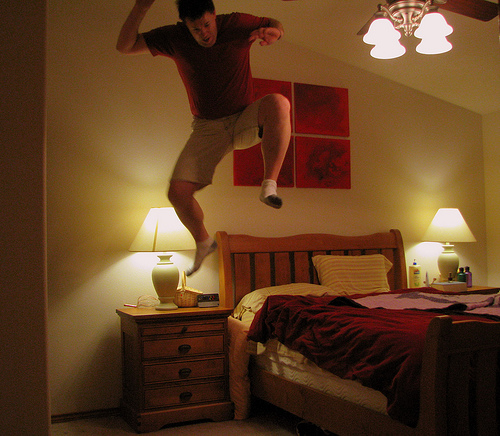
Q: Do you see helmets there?
A: No, there are no helmets.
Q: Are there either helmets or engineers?
A: No, there are no helmets or engineers.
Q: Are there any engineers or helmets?
A: No, there are no helmets or engineers.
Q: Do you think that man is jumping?
A: Yes, the man is jumping.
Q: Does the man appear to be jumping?
A: Yes, the man is jumping.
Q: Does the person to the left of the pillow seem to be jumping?
A: Yes, the man is jumping.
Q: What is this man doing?
A: The man is jumping.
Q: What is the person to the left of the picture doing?
A: The man is jumping.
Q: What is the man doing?
A: The man is jumping.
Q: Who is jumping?
A: The man is jumping.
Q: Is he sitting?
A: No, the man is jumping.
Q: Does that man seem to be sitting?
A: No, the man is jumping.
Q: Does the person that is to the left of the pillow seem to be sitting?
A: No, the man is jumping.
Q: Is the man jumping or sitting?
A: The man is jumping.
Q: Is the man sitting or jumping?
A: The man is jumping.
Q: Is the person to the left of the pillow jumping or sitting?
A: The man is jumping.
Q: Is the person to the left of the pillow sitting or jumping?
A: The man is jumping.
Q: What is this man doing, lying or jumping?
A: The man is jumping.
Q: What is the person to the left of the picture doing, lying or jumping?
A: The man is jumping.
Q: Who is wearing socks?
A: The man is wearing socks.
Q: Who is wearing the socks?
A: The man is wearing socks.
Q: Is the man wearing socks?
A: Yes, the man is wearing socks.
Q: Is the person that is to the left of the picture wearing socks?
A: Yes, the man is wearing socks.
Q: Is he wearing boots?
A: No, the man is wearing socks.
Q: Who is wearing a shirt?
A: The man is wearing a shirt.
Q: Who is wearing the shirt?
A: The man is wearing a shirt.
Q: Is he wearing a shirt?
A: Yes, the man is wearing a shirt.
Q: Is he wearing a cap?
A: No, the man is wearing a shirt.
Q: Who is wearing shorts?
A: The man is wearing shorts.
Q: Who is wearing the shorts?
A: The man is wearing shorts.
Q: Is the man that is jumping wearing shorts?
A: Yes, the man is wearing shorts.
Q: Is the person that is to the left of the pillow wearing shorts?
A: Yes, the man is wearing shorts.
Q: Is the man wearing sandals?
A: No, the man is wearing shorts.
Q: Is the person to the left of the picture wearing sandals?
A: No, the man is wearing shorts.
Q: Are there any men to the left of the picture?
A: Yes, there is a man to the left of the picture.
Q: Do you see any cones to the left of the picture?
A: No, there is a man to the left of the picture.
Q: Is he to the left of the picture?
A: Yes, the man is to the left of the picture.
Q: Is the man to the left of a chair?
A: No, the man is to the left of the picture.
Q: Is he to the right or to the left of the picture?
A: The man is to the left of the picture.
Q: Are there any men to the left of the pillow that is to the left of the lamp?
A: Yes, there is a man to the left of the pillow.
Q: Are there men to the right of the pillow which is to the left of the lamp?
A: No, the man is to the left of the pillow.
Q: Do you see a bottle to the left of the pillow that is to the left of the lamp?
A: No, there is a man to the left of the pillow.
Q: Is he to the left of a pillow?
A: Yes, the man is to the left of a pillow.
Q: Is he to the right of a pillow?
A: No, the man is to the left of a pillow.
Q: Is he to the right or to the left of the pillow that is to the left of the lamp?
A: The man is to the left of the pillow.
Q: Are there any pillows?
A: Yes, there is a pillow.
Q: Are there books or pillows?
A: Yes, there is a pillow.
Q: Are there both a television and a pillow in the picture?
A: No, there is a pillow but no televisions.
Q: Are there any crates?
A: No, there are no crates.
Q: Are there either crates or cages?
A: No, there are no crates or cages.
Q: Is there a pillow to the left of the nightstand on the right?
A: Yes, there is a pillow to the left of the nightstand.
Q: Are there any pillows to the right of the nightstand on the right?
A: No, the pillow is to the left of the nightstand.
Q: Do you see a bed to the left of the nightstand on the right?
A: No, there is a pillow to the left of the nightstand.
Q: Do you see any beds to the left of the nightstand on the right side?
A: No, there is a pillow to the left of the nightstand.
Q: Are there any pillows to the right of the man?
A: Yes, there is a pillow to the right of the man.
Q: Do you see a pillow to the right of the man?
A: Yes, there is a pillow to the right of the man.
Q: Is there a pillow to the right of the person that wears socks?
A: Yes, there is a pillow to the right of the man.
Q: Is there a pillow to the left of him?
A: No, the pillow is to the right of the man.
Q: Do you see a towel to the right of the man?
A: No, there is a pillow to the right of the man.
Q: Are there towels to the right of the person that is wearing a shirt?
A: No, there is a pillow to the right of the man.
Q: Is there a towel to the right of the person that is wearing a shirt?
A: No, there is a pillow to the right of the man.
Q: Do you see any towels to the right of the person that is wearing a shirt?
A: No, there is a pillow to the right of the man.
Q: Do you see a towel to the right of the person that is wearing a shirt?
A: No, there is a pillow to the right of the man.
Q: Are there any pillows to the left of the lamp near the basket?
A: No, the pillow is to the right of the lamp.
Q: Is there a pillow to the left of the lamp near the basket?
A: No, the pillow is to the right of the lamp.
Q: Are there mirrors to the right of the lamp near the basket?
A: No, there is a pillow to the right of the lamp.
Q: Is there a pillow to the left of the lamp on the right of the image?
A: Yes, there is a pillow to the left of the lamp.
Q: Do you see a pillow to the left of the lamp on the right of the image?
A: Yes, there is a pillow to the left of the lamp.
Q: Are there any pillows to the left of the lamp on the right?
A: Yes, there is a pillow to the left of the lamp.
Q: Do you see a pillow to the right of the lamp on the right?
A: No, the pillow is to the left of the lamp.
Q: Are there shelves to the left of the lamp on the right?
A: No, there is a pillow to the left of the lamp.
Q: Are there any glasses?
A: No, there are no glasses.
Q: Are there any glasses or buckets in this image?
A: No, there are no glasses or buckets.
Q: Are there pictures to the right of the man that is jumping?
A: Yes, there is a picture to the right of the man.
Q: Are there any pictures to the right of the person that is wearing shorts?
A: Yes, there is a picture to the right of the man.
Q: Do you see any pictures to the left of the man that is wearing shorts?
A: No, the picture is to the right of the man.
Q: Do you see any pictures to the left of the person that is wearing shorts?
A: No, the picture is to the right of the man.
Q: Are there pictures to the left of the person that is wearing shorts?
A: No, the picture is to the right of the man.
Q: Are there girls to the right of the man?
A: No, there is a picture to the right of the man.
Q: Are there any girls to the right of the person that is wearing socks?
A: No, there is a picture to the right of the man.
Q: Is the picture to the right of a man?
A: Yes, the picture is to the right of a man.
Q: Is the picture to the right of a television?
A: No, the picture is to the right of a man.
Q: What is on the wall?
A: The picture is on the wall.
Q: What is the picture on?
A: The picture is on the wall.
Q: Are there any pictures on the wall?
A: Yes, there is a picture on the wall.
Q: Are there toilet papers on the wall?
A: No, there is a picture on the wall.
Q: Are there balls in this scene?
A: No, there are no balls.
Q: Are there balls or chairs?
A: No, there are no balls or chairs.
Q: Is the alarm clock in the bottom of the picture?
A: Yes, the alarm clock is in the bottom of the image.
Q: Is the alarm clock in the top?
A: No, the alarm clock is in the bottom of the image.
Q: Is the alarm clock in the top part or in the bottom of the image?
A: The alarm clock is in the bottom of the image.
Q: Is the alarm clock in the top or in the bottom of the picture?
A: The alarm clock is in the bottom of the image.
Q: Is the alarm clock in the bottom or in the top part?
A: The alarm clock is in the bottom of the image.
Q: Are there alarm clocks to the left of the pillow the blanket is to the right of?
A: Yes, there is an alarm clock to the left of the pillow.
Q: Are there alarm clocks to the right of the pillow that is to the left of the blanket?
A: No, the alarm clock is to the left of the pillow.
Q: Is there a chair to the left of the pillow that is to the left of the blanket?
A: No, there is an alarm clock to the left of the pillow.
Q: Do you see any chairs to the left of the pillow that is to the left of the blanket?
A: No, there is an alarm clock to the left of the pillow.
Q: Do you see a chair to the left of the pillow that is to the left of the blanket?
A: No, there is an alarm clock to the left of the pillow.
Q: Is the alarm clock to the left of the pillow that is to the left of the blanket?
A: Yes, the alarm clock is to the left of the pillow.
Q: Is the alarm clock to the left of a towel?
A: No, the alarm clock is to the left of the pillow.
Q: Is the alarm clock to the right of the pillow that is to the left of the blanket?
A: No, the alarm clock is to the left of the pillow.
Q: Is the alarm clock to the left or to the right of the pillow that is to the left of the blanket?
A: The alarm clock is to the left of the pillow.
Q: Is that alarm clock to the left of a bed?
A: No, the alarm clock is to the left of the mattress.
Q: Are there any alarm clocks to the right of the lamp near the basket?
A: Yes, there is an alarm clock to the right of the lamp.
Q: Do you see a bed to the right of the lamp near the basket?
A: No, there is an alarm clock to the right of the lamp.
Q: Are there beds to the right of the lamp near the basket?
A: No, there is an alarm clock to the right of the lamp.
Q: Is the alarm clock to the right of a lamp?
A: Yes, the alarm clock is to the right of a lamp.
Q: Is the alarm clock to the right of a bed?
A: No, the alarm clock is to the right of a lamp.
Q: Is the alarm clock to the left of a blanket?
A: Yes, the alarm clock is to the left of a blanket.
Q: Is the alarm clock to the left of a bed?
A: No, the alarm clock is to the left of a blanket.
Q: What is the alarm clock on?
A: The alarm clock is on the nightstand.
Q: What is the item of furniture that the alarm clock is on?
A: The piece of furniture is a nightstand.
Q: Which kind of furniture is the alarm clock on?
A: The alarm clock is on the nightstand.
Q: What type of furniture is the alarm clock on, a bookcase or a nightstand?
A: The alarm clock is on a nightstand.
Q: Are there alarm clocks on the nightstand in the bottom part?
A: Yes, there is an alarm clock on the nightstand.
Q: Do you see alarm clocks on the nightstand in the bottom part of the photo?
A: Yes, there is an alarm clock on the nightstand.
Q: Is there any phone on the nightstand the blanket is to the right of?
A: No, there is an alarm clock on the nightstand.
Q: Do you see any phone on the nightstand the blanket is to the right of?
A: No, there is an alarm clock on the nightstand.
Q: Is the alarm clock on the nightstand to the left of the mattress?
A: Yes, the alarm clock is on the nightstand.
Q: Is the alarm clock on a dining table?
A: No, the alarm clock is on the nightstand.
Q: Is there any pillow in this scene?
A: Yes, there is a pillow.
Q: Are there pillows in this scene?
A: Yes, there is a pillow.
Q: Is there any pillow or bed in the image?
A: Yes, there is a pillow.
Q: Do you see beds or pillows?
A: Yes, there is a pillow.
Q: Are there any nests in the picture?
A: No, there are no nests.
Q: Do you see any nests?
A: No, there are no nests.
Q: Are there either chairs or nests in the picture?
A: No, there are no nests or chairs.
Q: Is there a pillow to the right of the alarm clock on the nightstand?
A: Yes, there is a pillow to the right of the alarm clock.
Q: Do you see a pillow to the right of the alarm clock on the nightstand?
A: Yes, there is a pillow to the right of the alarm clock.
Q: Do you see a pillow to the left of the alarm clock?
A: No, the pillow is to the right of the alarm clock.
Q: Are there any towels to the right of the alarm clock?
A: No, there is a pillow to the right of the alarm clock.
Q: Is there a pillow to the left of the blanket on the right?
A: Yes, there is a pillow to the left of the blanket.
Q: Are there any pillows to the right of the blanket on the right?
A: No, the pillow is to the left of the blanket.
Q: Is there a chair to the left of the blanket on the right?
A: No, there is a pillow to the left of the blanket.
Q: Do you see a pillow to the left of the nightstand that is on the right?
A: Yes, there is a pillow to the left of the nightstand.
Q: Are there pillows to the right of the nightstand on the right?
A: No, the pillow is to the left of the nightstand.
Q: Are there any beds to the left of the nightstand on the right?
A: No, there is a pillow to the left of the nightstand.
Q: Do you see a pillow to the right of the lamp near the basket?
A: Yes, there is a pillow to the right of the lamp.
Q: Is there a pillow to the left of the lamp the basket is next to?
A: No, the pillow is to the right of the lamp.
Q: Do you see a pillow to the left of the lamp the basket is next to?
A: No, the pillow is to the right of the lamp.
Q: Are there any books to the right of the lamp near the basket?
A: No, there is a pillow to the right of the lamp.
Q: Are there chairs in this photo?
A: No, there are no chairs.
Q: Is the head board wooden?
A: Yes, the head board is wooden.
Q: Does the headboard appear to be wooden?
A: Yes, the headboard is wooden.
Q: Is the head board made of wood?
A: Yes, the head board is made of wood.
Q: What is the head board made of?
A: The head board is made of wood.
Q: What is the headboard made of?
A: The head board is made of wood.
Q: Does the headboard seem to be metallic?
A: No, the headboard is wooden.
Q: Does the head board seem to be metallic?
A: No, the head board is wooden.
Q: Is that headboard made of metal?
A: No, the headboard is made of wood.